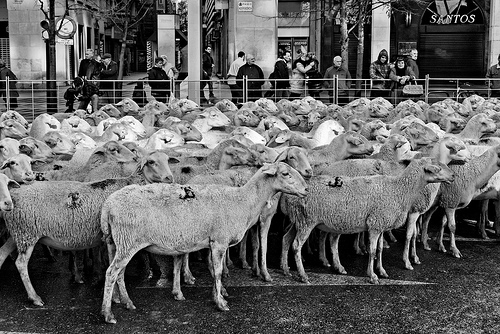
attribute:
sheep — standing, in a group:
[291, 152, 461, 289]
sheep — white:
[249, 159, 454, 270]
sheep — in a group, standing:
[101, 160, 309, 322]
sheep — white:
[189, 99, 231, 136]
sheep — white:
[296, 150, 451, 281]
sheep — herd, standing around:
[6, 90, 483, 252]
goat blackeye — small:
[278, 172, 290, 178]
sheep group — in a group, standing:
[0, 97, 497, 322]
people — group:
[51, 42, 433, 106]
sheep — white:
[28, 173, 185, 311]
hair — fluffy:
[1, 185, 138, 255]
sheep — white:
[89, 156, 331, 326]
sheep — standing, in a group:
[141, 122, 215, 154]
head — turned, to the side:
[7, 158, 40, 178]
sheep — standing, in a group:
[1, 93, 498, 322]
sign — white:
[406, 0, 494, 35]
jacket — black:
[225, 70, 261, 95]